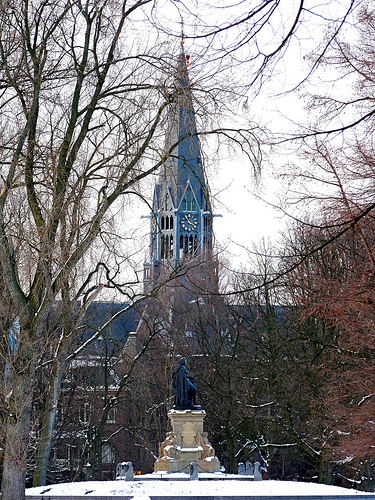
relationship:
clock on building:
[163, 207, 212, 244] [148, 19, 228, 348]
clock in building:
[163, 207, 212, 244] [148, 19, 228, 348]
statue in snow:
[162, 353, 221, 413] [185, 475, 247, 500]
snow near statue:
[185, 475, 247, 500] [162, 353, 221, 413]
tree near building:
[40, 27, 180, 228] [148, 19, 228, 348]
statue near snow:
[162, 353, 221, 413] [185, 475, 247, 500]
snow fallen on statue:
[142, 481, 257, 491] [162, 353, 221, 413]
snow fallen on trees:
[142, 481, 257, 491] [0, 238, 331, 407]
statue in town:
[171, 353, 203, 410] [0, 1, 362, 498]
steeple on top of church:
[132, 5, 222, 302] [5, 285, 318, 471]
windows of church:
[51, 393, 123, 422] [11, 287, 330, 481]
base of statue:
[149, 455, 222, 472] [145, 352, 224, 472]